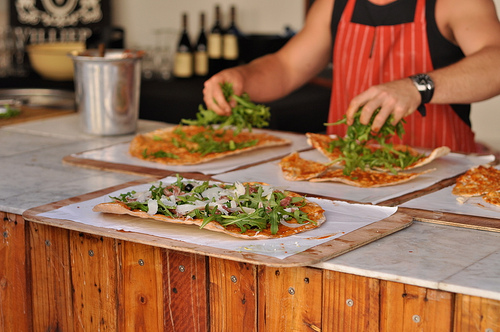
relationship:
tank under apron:
[328, 1, 476, 128] [327, 1, 478, 153]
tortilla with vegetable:
[87, 170, 330, 252] [110, 172, 315, 236]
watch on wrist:
[407, 69, 435, 117] [398, 64, 440, 119]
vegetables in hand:
[320, 106, 406, 152] [345, 72, 426, 140]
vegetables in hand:
[183, 84, 272, 137] [198, 65, 248, 117]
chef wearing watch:
[188, 2, 499, 155] [407, 69, 435, 117]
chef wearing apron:
[188, 2, 499, 155] [327, 1, 478, 153]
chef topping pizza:
[188, 2, 499, 155] [120, 117, 288, 169]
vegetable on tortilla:
[110, 172, 315, 236] [87, 170, 330, 252]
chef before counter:
[188, 2, 499, 155] [0, 107, 495, 330]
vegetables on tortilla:
[183, 84, 272, 137] [120, 117, 288, 169]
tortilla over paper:
[87, 170, 330, 252] [28, 171, 401, 270]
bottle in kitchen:
[171, 6, 195, 80] [3, 1, 497, 331]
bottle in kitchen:
[192, 12, 212, 80] [3, 1, 497, 331]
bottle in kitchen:
[209, 3, 223, 63] [3, 1, 497, 331]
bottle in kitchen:
[224, 4, 238, 62] [3, 1, 497, 331]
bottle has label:
[171, 6, 195, 80] [173, 49, 193, 78]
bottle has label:
[192, 12, 212, 80] [194, 51, 208, 75]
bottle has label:
[209, 3, 223, 63] [208, 31, 221, 62]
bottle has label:
[224, 4, 238, 62] [223, 32, 240, 60]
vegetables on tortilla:
[320, 106, 406, 152] [280, 128, 455, 194]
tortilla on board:
[87, 170, 330, 252] [22, 171, 416, 269]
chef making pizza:
[188, 2, 499, 155] [120, 117, 288, 169]